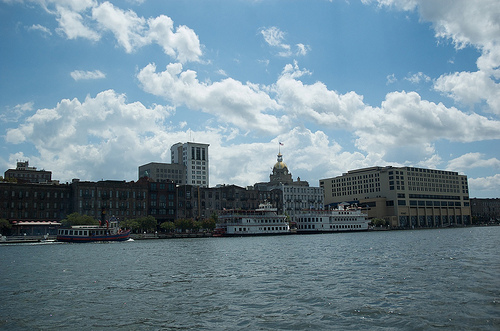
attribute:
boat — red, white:
[58, 217, 131, 240]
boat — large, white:
[222, 211, 291, 236]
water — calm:
[0, 223, 499, 329]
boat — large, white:
[286, 204, 370, 231]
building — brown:
[3, 182, 76, 239]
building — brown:
[71, 181, 145, 231]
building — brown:
[143, 174, 182, 234]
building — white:
[170, 140, 209, 188]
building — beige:
[317, 163, 475, 229]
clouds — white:
[0, 0, 498, 199]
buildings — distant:
[6, 109, 498, 287]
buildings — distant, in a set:
[1, 145, 498, 278]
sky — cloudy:
[11, 14, 498, 182]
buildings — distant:
[6, 128, 498, 262]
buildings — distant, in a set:
[4, 114, 498, 270]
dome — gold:
[259, 126, 305, 198]